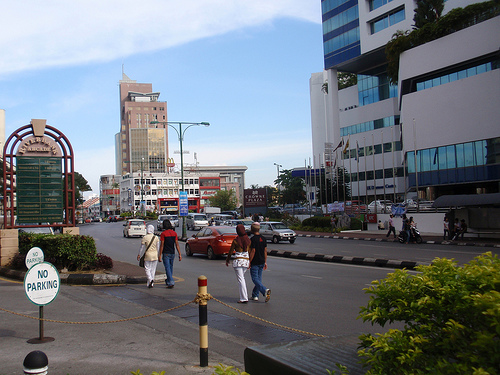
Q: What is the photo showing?
A: It is showing a street.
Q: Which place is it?
A: It is a street.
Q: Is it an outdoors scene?
A: Yes, it is outdoors.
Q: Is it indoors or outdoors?
A: It is outdoors.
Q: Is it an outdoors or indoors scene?
A: It is outdoors.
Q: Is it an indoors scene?
A: No, it is outdoors.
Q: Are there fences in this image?
A: No, there are no fences.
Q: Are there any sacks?
A: No, there are no sacks.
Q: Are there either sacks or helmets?
A: No, there are no sacks or helmets.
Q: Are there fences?
A: No, there are no fences.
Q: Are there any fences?
A: No, there are no fences.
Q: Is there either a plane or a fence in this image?
A: No, there are no fences or airplanes.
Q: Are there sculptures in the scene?
A: No, there are no sculptures.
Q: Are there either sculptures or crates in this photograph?
A: No, there are no sculptures or crates.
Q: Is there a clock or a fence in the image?
A: No, there are no fences or clocks.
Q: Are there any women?
A: Yes, there is a woman.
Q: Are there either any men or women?
A: Yes, there is a woman.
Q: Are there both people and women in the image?
A: Yes, there are both a woman and a person.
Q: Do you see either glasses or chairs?
A: No, there are no glasses or chairs.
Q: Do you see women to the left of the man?
A: Yes, there is a woman to the left of the man.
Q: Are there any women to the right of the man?
A: No, the woman is to the left of the man.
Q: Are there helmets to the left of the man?
A: No, there is a woman to the left of the man.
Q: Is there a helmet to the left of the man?
A: No, there is a woman to the left of the man.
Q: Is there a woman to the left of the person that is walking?
A: Yes, there is a woman to the left of the person.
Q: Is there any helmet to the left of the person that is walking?
A: No, there is a woman to the left of the person.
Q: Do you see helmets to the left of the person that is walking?
A: No, there is a woman to the left of the person.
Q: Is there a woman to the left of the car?
A: Yes, there is a woman to the left of the car.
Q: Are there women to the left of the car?
A: Yes, there is a woman to the left of the car.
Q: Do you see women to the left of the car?
A: Yes, there is a woman to the left of the car.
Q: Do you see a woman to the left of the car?
A: Yes, there is a woman to the left of the car.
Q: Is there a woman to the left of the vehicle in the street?
A: Yes, there is a woman to the left of the car.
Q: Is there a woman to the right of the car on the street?
A: No, the woman is to the left of the car.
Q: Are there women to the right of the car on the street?
A: No, the woman is to the left of the car.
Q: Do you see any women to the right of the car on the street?
A: No, the woman is to the left of the car.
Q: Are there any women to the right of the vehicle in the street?
A: No, the woman is to the left of the car.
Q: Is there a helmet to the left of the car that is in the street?
A: No, there is a woman to the left of the car.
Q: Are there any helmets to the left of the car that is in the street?
A: No, there is a woman to the left of the car.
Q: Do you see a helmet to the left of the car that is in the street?
A: No, there is a woman to the left of the car.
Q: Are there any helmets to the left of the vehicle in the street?
A: No, there is a woman to the left of the car.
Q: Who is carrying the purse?
A: The woman is carrying the purse.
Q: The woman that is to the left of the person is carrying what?
A: The woman is carrying a purse.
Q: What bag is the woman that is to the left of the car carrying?
A: The woman is carrying a purse.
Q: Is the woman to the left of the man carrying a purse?
A: Yes, the woman is carrying a purse.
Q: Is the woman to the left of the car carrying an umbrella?
A: No, the woman is carrying a purse.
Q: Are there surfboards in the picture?
A: No, there are no surfboards.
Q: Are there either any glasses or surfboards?
A: No, there are no surfboards or glasses.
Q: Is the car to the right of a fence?
A: No, the car is to the right of the vehicle.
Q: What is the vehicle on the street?
A: The vehicle is a car.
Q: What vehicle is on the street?
A: The vehicle is a car.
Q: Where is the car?
A: The car is on the street.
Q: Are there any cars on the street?
A: Yes, there is a car on the street.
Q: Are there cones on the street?
A: No, there is a car on the street.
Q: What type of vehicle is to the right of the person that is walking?
A: The vehicle is a car.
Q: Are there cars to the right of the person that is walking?
A: Yes, there is a car to the right of the person.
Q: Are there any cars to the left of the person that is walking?
A: No, the car is to the right of the person.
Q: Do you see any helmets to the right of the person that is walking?
A: No, there is a car to the right of the person.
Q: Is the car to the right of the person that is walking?
A: Yes, the car is to the right of the person.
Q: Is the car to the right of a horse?
A: No, the car is to the right of the person.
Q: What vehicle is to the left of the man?
A: The vehicle is a car.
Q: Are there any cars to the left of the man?
A: Yes, there is a car to the left of the man.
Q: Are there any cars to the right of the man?
A: No, the car is to the left of the man.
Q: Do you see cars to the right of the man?
A: No, the car is to the left of the man.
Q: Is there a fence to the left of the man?
A: No, there is a car to the left of the man.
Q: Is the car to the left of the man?
A: Yes, the car is to the left of the man.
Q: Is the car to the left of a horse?
A: No, the car is to the left of the man.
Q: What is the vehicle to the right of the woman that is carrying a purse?
A: The vehicle is a car.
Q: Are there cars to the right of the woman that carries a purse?
A: Yes, there is a car to the right of the woman.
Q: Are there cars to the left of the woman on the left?
A: No, the car is to the right of the woman.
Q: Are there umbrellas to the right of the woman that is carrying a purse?
A: No, there is a car to the right of the woman.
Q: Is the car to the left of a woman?
A: No, the car is to the right of a woman.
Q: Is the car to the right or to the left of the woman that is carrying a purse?
A: The car is to the right of the woman.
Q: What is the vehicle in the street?
A: The vehicle is a car.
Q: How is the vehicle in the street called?
A: The vehicle is a car.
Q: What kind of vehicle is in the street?
A: The vehicle is a car.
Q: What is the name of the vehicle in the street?
A: The vehicle is a car.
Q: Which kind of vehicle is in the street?
A: The vehicle is a car.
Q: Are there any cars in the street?
A: Yes, there is a car in the street.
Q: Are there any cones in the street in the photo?
A: No, there is a car in the street.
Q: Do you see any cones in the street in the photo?
A: No, there is a car in the street.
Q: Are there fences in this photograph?
A: No, there are no fences.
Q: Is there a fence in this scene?
A: No, there are no fences.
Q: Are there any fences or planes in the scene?
A: No, there are no fences or planes.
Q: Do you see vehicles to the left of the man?
A: Yes, there is a vehicle to the left of the man.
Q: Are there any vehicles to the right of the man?
A: No, the vehicle is to the left of the man.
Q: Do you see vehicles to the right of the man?
A: No, the vehicle is to the left of the man.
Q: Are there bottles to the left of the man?
A: No, there is a vehicle to the left of the man.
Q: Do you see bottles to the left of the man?
A: No, there is a vehicle to the left of the man.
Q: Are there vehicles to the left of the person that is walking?
A: Yes, there is a vehicle to the left of the person.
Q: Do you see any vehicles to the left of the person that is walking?
A: Yes, there is a vehicle to the left of the person.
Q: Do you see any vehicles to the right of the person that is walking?
A: No, the vehicle is to the left of the person.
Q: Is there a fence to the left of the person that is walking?
A: No, there is a vehicle to the left of the person.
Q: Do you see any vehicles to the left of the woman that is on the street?
A: Yes, there is a vehicle to the left of the woman.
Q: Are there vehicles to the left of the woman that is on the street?
A: Yes, there is a vehicle to the left of the woman.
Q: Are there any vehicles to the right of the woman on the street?
A: No, the vehicle is to the left of the woman.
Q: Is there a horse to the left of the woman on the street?
A: No, there is a vehicle to the left of the woman.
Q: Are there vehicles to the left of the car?
A: Yes, there is a vehicle to the left of the car.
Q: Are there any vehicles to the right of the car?
A: No, the vehicle is to the left of the car.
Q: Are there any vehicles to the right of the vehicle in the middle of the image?
A: No, the vehicle is to the left of the car.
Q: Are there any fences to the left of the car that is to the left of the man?
A: No, there is a vehicle to the left of the car.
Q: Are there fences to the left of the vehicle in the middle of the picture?
A: No, there is a vehicle to the left of the car.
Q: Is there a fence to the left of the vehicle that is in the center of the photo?
A: No, there is a vehicle to the left of the car.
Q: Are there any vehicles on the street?
A: Yes, there is a vehicle on the street.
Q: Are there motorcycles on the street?
A: No, there is a vehicle on the street.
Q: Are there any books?
A: No, there are no books.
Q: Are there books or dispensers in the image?
A: No, there are no books or dispensers.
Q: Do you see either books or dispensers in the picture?
A: No, there are no books or dispensers.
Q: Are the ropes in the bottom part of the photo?
A: Yes, the ropes are in the bottom of the image.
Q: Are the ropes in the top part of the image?
A: No, the ropes are in the bottom of the image.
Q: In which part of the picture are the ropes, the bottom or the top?
A: The ropes are in the bottom of the image.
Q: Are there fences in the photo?
A: No, there are no fences.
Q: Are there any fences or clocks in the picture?
A: No, there are no fences or clocks.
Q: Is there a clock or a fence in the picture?
A: No, there are no fences or clocks.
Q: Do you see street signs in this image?
A: Yes, there is a street sign.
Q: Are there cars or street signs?
A: Yes, there is a street sign.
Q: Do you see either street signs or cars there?
A: Yes, there is a street sign.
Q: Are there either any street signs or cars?
A: Yes, there is a street sign.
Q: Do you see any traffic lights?
A: No, there are no traffic lights.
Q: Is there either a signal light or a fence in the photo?
A: No, there are no traffic lights or fences.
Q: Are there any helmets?
A: No, there are no helmets.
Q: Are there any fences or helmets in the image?
A: No, there are no helmets or fences.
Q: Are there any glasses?
A: No, there are no glasses.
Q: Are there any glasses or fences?
A: No, there are no glasses or fences.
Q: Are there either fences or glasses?
A: No, there are no glasses or fences.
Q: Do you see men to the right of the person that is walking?
A: Yes, there is a man to the right of the person.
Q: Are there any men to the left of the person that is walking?
A: No, the man is to the right of the person.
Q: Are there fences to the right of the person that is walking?
A: No, there is a man to the right of the person.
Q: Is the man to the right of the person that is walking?
A: Yes, the man is to the right of the person.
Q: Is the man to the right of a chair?
A: No, the man is to the right of the person.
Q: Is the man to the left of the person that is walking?
A: No, the man is to the right of the person.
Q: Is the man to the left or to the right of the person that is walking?
A: The man is to the right of the person.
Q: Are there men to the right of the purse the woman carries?
A: Yes, there is a man to the right of the purse.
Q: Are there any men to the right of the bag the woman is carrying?
A: Yes, there is a man to the right of the purse.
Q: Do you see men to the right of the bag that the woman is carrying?
A: Yes, there is a man to the right of the purse.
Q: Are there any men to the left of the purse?
A: No, the man is to the right of the purse.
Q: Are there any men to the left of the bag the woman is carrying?
A: No, the man is to the right of the purse.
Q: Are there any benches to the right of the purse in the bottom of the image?
A: No, there is a man to the right of the purse.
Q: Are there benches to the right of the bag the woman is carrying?
A: No, there is a man to the right of the purse.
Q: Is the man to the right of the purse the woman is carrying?
A: Yes, the man is to the right of the purse.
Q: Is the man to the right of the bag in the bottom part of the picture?
A: Yes, the man is to the right of the purse.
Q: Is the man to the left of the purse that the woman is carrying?
A: No, the man is to the right of the purse.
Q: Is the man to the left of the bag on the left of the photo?
A: No, the man is to the right of the purse.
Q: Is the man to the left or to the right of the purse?
A: The man is to the right of the purse.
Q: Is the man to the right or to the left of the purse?
A: The man is to the right of the purse.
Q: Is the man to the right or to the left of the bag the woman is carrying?
A: The man is to the right of the purse.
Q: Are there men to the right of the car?
A: Yes, there is a man to the right of the car.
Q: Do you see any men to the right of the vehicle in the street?
A: Yes, there is a man to the right of the car.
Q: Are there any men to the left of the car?
A: No, the man is to the right of the car.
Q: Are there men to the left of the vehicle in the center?
A: No, the man is to the right of the car.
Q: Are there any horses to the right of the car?
A: No, there is a man to the right of the car.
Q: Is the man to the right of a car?
A: Yes, the man is to the right of a car.